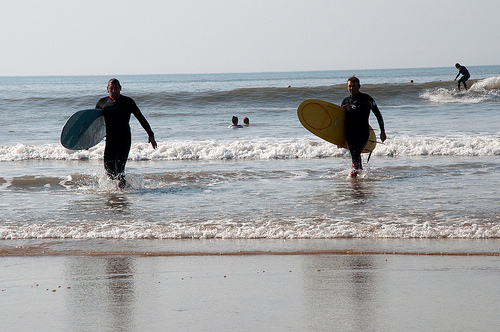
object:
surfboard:
[298, 99, 379, 152]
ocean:
[0, 66, 499, 238]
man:
[338, 74, 387, 179]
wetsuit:
[341, 92, 384, 162]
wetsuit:
[93, 94, 155, 183]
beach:
[0, 237, 500, 332]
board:
[60, 109, 107, 150]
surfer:
[453, 63, 470, 90]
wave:
[420, 77, 500, 104]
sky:
[0, 2, 500, 82]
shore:
[0, 179, 500, 256]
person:
[95, 78, 158, 189]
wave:
[0, 134, 500, 160]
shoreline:
[0, 236, 499, 256]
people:
[227, 115, 244, 128]